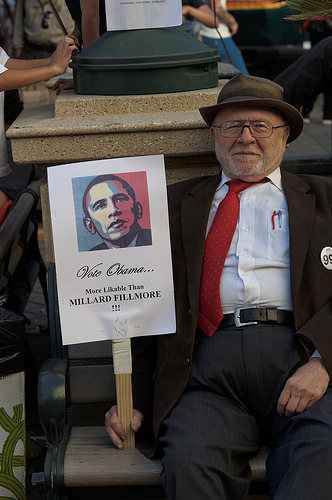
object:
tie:
[198, 177, 270, 338]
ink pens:
[270, 209, 277, 230]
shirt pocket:
[266, 211, 292, 264]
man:
[102, 71, 332, 498]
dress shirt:
[202, 163, 292, 316]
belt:
[204, 305, 294, 330]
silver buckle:
[231, 306, 258, 329]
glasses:
[211, 118, 289, 141]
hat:
[198, 71, 309, 146]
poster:
[45, 154, 179, 345]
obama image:
[70, 171, 154, 253]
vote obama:
[71, 260, 158, 281]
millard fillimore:
[68, 290, 163, 308]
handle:
[113, 374, 137, 447]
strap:
[43, 0, 67, 37]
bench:
[40, 335, 331, 498]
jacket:
[153, 166, 332, 400]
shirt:
[11, 1, 76, 53]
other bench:
[0, 173, 51, 375]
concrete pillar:
[4, 86, 221, 166]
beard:
[214, 136, 286, 181]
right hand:
[105, 406, 142, 446]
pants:
[156, 306, 331, 498]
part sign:
[103, 0, 183, 30]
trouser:
[275, 31, 332, 121]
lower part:
[43, 431, 330, 500]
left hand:
[275, 360, 331, 416]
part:
[191, 400, 240, 451]